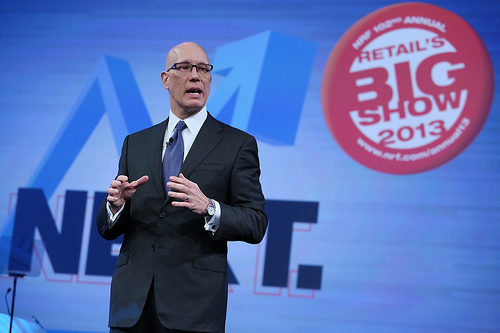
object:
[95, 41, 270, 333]
man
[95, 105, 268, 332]
suit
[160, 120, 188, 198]
tie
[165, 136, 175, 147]
microphone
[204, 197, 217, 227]
watch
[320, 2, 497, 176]
sign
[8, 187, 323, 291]
writing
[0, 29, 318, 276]
arrow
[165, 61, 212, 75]
glasses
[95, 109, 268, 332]
jacket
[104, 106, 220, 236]
shirt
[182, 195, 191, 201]
ring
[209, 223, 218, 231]
button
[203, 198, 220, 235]
sleeve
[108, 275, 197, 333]
pants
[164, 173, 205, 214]
hands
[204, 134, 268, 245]
arms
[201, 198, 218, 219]
wrist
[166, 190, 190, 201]
finger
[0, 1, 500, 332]
screen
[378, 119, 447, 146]
year